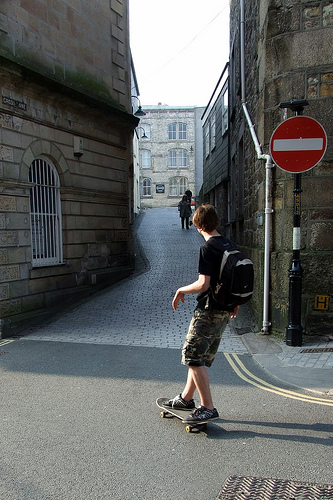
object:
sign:
[268, 114, 328, 172]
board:
[156, 396, 209, 433]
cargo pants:
[180, 304, 228, 365]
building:
[137, 112, 194, 212]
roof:
[135, 105, 196, 110]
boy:
[171, 204, 254, 424]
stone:
[262, 347, 295, 366]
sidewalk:
[241, 326, 322, 374]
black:
[80, 443, 128, 475]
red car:
[189, 196, 195, 206]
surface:
[62, 6, 95, 36]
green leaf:
[46, 351, 158, 443]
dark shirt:
[196, 234, 230, 311]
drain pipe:
[239, 0, 273, 332]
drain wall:
[228, 0, 330, 342]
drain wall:
[1, 1, 137, 335]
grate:
[215, 474, 332, 498]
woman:
[177, 189, 192, 228]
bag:
[188, 217, 192, 226]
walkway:
[127, 184, 238, 328]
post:
[285, 173, 306, 351]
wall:
[0, 6, 131, 283]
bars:
[27, 158, 58, 257]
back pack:
[213, 244, 255, 311]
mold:
[1, 36, 119, 104]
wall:
[1, 0, 84, 36]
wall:
[227, 1, 321, 336]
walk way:
[20, 204, 253, 351]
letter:
[316, 296, 326, 309]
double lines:
[222, 352, 333, 407]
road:
[1, 338, 332, 496]